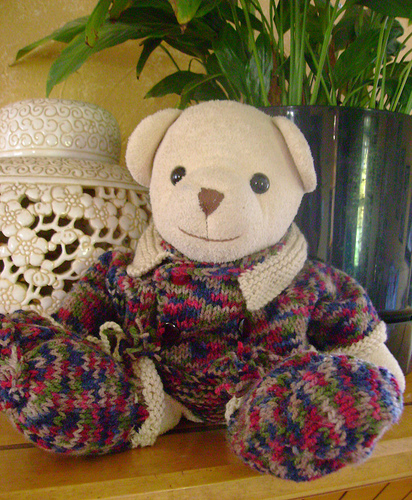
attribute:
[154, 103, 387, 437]
teddy bear — white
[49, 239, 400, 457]
outfit — multicolor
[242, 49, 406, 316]
planter — black, reflective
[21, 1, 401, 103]
plant — green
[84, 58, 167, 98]
walks — yellow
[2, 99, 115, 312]
vase — white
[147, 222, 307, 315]
collar — white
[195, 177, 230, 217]
nose — brown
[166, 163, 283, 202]
eyes — black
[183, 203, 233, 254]
mouth — thin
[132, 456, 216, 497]
fish — cut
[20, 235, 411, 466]
sweater — multicolor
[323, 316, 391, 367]
cuff — white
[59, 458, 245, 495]
table — wood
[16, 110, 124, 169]
pattern — circular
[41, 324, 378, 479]
shoes — knit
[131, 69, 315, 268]
face — round, beige